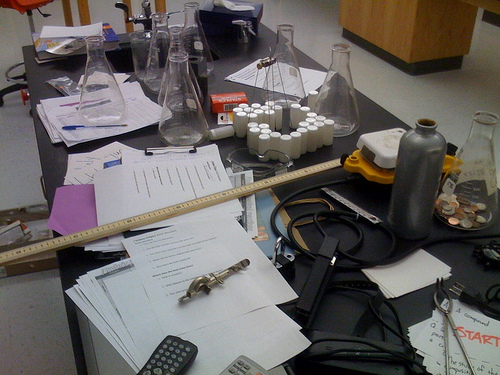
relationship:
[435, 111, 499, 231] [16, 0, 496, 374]
beaker on desk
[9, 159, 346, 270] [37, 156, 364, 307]
ruler on table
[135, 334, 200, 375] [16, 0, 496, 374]
calculator on desk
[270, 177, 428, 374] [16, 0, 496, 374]
cable are on desk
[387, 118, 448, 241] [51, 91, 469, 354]
bottle on table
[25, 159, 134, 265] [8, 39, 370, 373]
paper on table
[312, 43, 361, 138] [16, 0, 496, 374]
beakers on desk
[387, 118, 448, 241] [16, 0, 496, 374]
bottle on desk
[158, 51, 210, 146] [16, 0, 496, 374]
beaker on desk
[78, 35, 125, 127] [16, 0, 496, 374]
beakers on desk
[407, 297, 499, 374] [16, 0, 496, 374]
paper are on desk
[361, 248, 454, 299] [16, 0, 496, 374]
papers are on desk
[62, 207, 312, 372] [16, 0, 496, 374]
papers are on desk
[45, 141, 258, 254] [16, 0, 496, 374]
paper are on desk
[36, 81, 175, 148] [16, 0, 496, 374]
papers are on desk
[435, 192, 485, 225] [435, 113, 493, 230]
coins are in jar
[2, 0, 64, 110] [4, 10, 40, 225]
chair on floor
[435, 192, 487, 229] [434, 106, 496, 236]
coins at bottom of jar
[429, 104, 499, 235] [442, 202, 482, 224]
beaker full of coins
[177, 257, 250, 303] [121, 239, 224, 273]
compass on paper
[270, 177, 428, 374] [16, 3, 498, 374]
cable on desk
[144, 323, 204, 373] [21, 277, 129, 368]
calculator on desk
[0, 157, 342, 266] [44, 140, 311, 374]
ruler among papers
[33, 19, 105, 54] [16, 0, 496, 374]
textbook on edge of desk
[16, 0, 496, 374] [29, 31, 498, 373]
desk cluttered with tools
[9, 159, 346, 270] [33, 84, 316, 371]
ruler on top of papers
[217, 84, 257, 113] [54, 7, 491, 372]
red box under table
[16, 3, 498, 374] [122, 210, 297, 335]
desk with papers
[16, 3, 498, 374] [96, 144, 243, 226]
desk with papers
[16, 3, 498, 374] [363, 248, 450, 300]
desk with papers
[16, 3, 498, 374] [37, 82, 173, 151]
desk with papers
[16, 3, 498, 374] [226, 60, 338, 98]
desk with papers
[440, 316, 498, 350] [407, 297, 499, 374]
red ink on paper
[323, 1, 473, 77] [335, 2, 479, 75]
bottom of desk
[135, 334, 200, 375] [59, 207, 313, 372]
calculator on top of papers